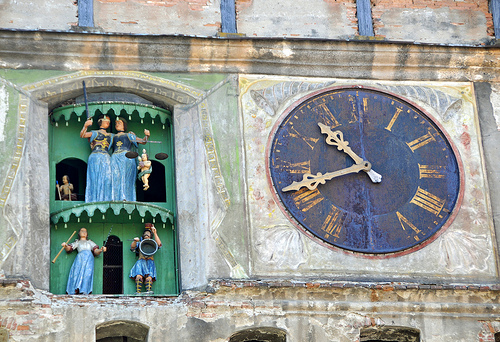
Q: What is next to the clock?
A: A carving of people.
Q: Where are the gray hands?
A: On the clock.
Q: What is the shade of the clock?
A: Black.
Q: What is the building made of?
A: Stone.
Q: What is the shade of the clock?
A: Black.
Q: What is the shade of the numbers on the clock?
A: Gold.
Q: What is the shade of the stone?
A: Gray.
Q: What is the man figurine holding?
A: Drum.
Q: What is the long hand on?
A: IX.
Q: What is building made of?
A: Stone.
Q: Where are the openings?
A: Windows.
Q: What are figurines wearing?
A: Blue.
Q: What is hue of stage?
A: Green.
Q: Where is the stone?
A: On building.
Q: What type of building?
A: Classic.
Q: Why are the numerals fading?
A: Old.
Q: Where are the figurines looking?
A: At each other.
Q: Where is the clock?
A: On building.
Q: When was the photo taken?
A: Daylight.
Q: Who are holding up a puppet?
A: Two women.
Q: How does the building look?
A: Old.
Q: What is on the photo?
A: Dramatic scene.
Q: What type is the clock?
A: Numerical.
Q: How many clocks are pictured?
A: One.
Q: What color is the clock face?
A: Black.